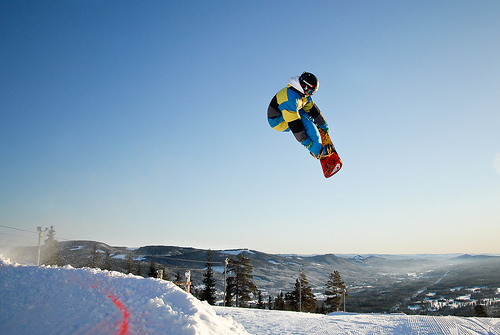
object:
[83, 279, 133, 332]
paint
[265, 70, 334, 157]
snowboarder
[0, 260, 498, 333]
cliff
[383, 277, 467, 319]
roadway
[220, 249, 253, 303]
tree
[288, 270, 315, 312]
tree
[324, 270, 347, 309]
tree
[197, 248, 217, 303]
tree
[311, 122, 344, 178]
snowboard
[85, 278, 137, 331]
line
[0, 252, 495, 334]
snow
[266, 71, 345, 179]
man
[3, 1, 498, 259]
sky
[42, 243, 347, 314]
trees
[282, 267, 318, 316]
evergreen tree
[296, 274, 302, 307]
evergreen tree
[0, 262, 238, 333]
snowpile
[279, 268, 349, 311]
pine trees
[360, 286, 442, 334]
ski path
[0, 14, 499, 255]
cloudless sky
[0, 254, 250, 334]
snow drift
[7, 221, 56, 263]
power line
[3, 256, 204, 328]
ski slope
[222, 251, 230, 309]
pole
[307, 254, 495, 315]
hillside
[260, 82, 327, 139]
gear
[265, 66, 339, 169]
person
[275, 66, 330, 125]
athlete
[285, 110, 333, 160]
pants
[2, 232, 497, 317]
mountains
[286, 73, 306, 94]
hood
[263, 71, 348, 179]
snowboarder